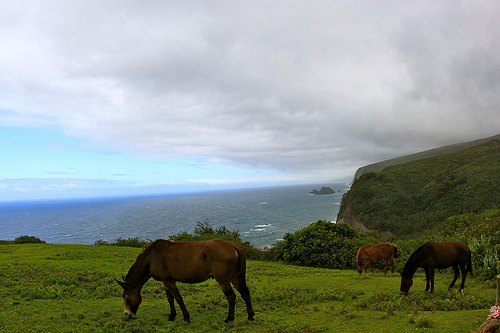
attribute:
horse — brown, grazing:
[399, 239, 475, 294]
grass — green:
[0, 242, 500, 332]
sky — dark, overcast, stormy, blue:
[1, 0, 500, 202]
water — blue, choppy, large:
[0, 180, 351, 248]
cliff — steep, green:
[334, 134, 499, 243]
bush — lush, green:
[280, 218, 365, 269]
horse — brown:
[114, 237, 257, 322]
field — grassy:
[1, 243, 500, 331]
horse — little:
[354, 240, 399, 276]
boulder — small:
[310, 185, 334, 195]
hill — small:
[1, 207, 499, 332]